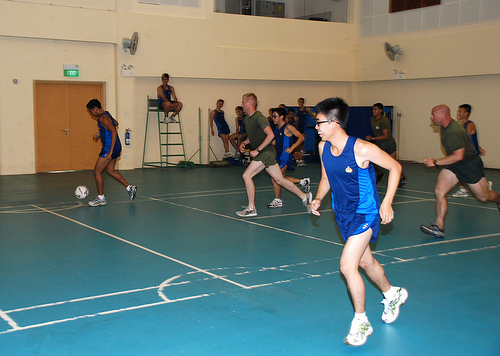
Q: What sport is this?
A: Soccer.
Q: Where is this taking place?
A: Soccer court.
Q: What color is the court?
A: Green.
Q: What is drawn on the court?
A: White lines.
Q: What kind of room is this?
A: Gym.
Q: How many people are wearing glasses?
A: Two.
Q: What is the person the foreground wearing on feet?
A: A pair of green and white sneakers.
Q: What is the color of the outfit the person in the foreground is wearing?
A: Dark blue and light blue.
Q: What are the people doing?
A: Playing a sport.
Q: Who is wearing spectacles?
A: Boy in blue uniform.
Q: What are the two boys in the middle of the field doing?
A: Playing soccer.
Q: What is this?
A: In door gym floor.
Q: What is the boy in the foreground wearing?
A: Athletic gear.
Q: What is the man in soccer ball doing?
A: He is dribbling soccer ball.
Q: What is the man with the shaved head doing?
A: THe man with the shaved head is running.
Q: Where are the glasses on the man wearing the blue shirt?
A: The glasses are on his smiling face.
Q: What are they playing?
A: Soccer.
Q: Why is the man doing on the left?
A: Kicking the ball.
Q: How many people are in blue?
A: 4.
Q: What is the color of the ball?
A: White.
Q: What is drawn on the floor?
A: Lines.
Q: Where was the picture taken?
A: Inside the gym.